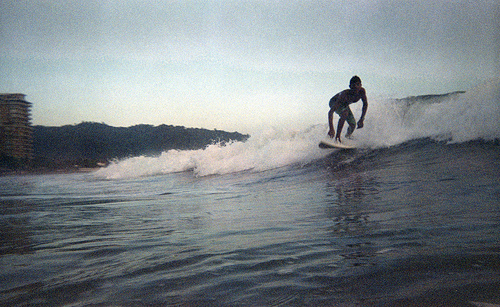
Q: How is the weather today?
A: It is overcast.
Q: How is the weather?
A: It is overcast.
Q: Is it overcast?
A: Yes, it is overcast.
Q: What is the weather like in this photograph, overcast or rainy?
A: It is overcast.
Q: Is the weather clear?
A: No, it is overcast.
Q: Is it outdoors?
A: Yes, it is outdoors.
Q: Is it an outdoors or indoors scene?
A: It is outdoors.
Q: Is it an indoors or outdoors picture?
A: It is outdoors.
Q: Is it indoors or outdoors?
A: It is outdoors.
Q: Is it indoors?
A: No, it is outdoors.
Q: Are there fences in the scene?
A: No, there are no fences.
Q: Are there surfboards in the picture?
A: Yes, there is a surfboard.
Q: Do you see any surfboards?
A: Yes, there is a surfboard.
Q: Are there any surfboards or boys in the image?
A: Yes, there is a surfboard.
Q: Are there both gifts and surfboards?
A: No, there is a surfboard but no gifts.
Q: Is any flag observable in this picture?
A: No, there are no flags.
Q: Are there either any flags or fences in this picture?
A: No, there are no flags or fences.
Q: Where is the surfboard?
A: The surfboard is in the water.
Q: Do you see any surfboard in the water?
A: Yes, there is a surfboard in the water.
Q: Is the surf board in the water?
A: Yes, the surf board is in the water.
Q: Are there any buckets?
A: No, there are no buckets.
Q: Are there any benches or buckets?
A: No, there are no buckets or benches.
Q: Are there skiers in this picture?
A: No, there are no skiers.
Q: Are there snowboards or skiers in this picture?
A: No, there are no skiers or snowboards.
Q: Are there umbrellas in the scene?
A: No, there are no umbrellas.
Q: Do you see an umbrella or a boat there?
A: No, there are no umbrellas or boats.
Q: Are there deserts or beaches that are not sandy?
A: No, there is a beach but it is sandy.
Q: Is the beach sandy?
A: Yes, the beach is sandy.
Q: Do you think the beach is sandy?
A: Yes, the beach is sandy.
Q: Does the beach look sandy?
A: Yes, the beach is sandy.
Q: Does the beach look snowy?
A: No, the beach is sandy.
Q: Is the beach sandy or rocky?
A: The beach is sandy.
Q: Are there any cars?
A: No, there are no cars.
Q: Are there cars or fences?
A: No, there are no cars or fences.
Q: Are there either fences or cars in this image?
A: No, there are no cars or fences.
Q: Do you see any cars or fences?
A: No, there are no cars or fences.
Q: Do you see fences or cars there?
A: No, there are no cars or fences.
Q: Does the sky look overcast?
A: Yes, the sky is overcast.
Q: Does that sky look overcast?
A: Yes, the sky is overcast.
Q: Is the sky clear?
A: No, the sky is overcast.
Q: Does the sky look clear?
A: No, the sky is overcast.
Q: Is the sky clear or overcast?
A: The sky is overcast.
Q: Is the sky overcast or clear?
A: The sky is overcast.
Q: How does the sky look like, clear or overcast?
A: The sky is overcast.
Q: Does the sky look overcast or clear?
A: The sky is overcast.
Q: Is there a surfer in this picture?
A: Yes, there is a surfer.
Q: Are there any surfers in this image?
A: Yes, there is a surfer.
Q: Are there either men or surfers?
A: Yes, there is a surfer.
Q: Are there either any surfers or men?
A: Yes, there is a surfer.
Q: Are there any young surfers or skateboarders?
A: Yes, there is a young surfer.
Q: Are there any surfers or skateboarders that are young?
A: Yes, the surfer is young.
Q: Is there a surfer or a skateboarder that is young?
A: Yes, the surfer is young.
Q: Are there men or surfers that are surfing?
A: Yes, the surfer is surfing.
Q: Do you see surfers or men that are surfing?
A: Yes, the surfer is surfing.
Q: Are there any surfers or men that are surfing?
A: Yes, the surfer is surfing.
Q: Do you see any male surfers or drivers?
A: Yes, there is a male surfer.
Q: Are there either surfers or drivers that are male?
A: Yes, the surfer is male.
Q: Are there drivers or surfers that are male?
A: Yes, the surfer is male.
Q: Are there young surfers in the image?
A: Yes, there is a young surfer.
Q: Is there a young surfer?
A: Yes, there is a young surfer.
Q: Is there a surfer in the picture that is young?
A: Yes, there is a surfer that is young.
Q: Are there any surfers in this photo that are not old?
A: Yes, there is an young surfer.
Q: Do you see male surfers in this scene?
A: Yes, there is a male surfer.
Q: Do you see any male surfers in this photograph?
A: Yes, there is a male surfer.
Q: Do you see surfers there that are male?
A: Yes, there is a surfer that is male.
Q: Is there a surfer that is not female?
A: Yes, there is a male surfer.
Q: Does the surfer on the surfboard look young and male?
A: Yes, the surfer is young and male.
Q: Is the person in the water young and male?
A: Yes, the surfer is young and male.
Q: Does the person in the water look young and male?
A: Yes, the surfer is young and male.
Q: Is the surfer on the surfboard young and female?
A: No, the surfer is young but male.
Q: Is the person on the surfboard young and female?
A: No, the surfer is young but male.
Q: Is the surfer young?
A: Yes, the surfer is young.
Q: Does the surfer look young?
A: Yes, the surfer is young.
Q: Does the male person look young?
A: Yes, the surfer is young.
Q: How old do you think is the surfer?
A: The surfer is young.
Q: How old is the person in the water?
A: The surfer is young.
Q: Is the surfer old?
A: No, the surfer is young.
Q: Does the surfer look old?
A: No, the surfer is young.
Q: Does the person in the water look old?
A: No, the surfer is young.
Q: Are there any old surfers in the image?
A: No, there is a surfer but he is young.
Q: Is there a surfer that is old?
A: No, there is a surfer but he is young.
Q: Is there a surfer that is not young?
A: No, there is a surfer but he is young.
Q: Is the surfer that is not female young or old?
A: The surfer is young.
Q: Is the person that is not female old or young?
A: The surfer is young.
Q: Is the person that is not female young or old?
A: The surfer is young.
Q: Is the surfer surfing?
A: Yes, the surfer is surfing.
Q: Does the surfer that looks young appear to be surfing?
A: Yes, the surfer is surfing.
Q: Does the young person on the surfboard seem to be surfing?
A: Yes, the surfer is surfing.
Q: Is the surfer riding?
A: No, the surfer is surfing.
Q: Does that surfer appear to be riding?
A: No, the surfer is surfing.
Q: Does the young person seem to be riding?
A: No, the surfer is surfing.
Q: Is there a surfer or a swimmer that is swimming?
A: No, there is a surfer but he is surfing.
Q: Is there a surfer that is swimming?
A: No, there is a surfer but he is surfing.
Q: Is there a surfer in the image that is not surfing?
A: No, there is a surfer but he is surfing.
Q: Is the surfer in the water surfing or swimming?
A: The surfer is surfing.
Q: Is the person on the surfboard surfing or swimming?
A: The surfer is surfing.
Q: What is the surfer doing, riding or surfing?
A: The surfer is surfing.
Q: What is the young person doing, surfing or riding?
A: The surfer is surfing.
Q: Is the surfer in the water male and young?
A: Yes, the surfer is male and young.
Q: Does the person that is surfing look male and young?
A: Yes, the surfer is male and young.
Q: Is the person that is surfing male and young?
A: Yes, the surfer is male and young.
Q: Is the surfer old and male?
A: No, the surfer is male but young.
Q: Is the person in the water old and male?
A: No, the surfer is male but young.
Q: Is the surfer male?
A: Yes, the surfer is male.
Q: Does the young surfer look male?
A: Yes, the surfer is male.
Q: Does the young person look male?
A: Yes, the surfer is male.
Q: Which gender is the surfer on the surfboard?
A: The surfer is male.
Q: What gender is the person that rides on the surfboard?
A: The surfer is male.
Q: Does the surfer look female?
A: No, the surfer is male.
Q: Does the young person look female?
A: No, the surfer is male.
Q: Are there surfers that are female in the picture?
A: No, there is a surfer but he is male.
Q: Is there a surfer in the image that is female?
A: No, there is a surfer but he is male.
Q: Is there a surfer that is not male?
A: No, there is a surfer but he is male.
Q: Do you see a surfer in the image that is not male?
A: No, there is a surfer but he is male.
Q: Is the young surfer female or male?
A: The surfer is male.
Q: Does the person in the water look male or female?
A: The surfer is male.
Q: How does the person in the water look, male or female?
A: The surfer is male.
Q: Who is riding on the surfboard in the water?
A: The surfer is riding on the surfboard.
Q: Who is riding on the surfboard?
A: The surfer is riding on the surfboard.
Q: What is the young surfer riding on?
A: The surfer is riding on the surf board.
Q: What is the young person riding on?
A: The surfer is riding on the surf board.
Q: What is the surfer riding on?
A: The surfer is riding on the surf board.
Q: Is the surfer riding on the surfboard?
A: Yes, the surfer is riding on the surfboard.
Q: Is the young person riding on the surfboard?
A: Yes, the surfer is riding on the surfboard.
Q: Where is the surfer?
A: The surfer is in the water.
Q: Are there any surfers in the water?
A: Yes, there is a surfer in the water.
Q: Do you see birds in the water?
A: No, there is a surfer in the water.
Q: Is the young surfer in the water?
A: Yes, the surfer is in the water.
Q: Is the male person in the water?
A: Yes, the surfer is in the water.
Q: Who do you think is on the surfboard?
A: The surfer is on the surfboard.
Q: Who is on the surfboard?
A: The surfer is on the surfboard.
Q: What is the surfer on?
A: The surfer is on the surfboard.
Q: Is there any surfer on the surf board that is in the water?
A: Yes, there is a surfer on the surfboard.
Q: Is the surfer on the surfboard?
A: Yes, the surfer is on the surfboard.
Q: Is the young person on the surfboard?
A: Yes, the surfer is on the surfboard.